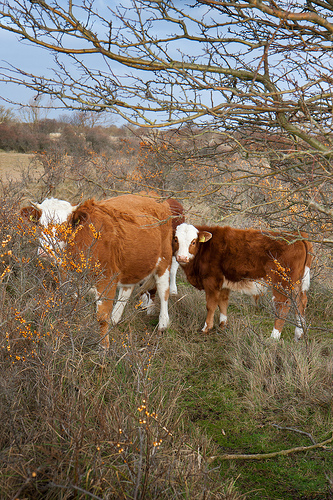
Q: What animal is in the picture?
A: Cow.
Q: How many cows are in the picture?
A: Two.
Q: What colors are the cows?
A: Brown and White.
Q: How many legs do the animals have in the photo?
A: Four.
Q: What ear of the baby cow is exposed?
A: Left.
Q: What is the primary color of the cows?
A: Brown.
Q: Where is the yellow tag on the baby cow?
A: In her ear.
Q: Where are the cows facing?
A: The Camera.